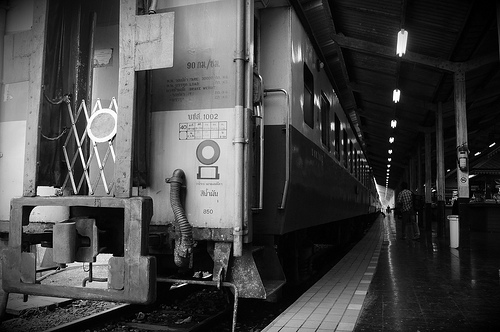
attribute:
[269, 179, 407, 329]
surface — tile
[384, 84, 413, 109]
light — small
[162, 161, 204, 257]
pipe — black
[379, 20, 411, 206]
lights — tube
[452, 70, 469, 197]
post — wall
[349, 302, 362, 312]
tile — white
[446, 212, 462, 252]
white trashcan — trash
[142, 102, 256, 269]
electrical system — very old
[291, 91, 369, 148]
window — small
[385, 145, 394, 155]
light — small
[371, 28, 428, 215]
lights —  ceiling's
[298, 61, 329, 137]
window — small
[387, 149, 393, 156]
light — small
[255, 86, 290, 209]
rail — hand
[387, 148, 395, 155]
light — small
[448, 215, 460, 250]
trash can — white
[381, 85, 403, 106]
light — small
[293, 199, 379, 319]
color — different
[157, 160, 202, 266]
hose — coil